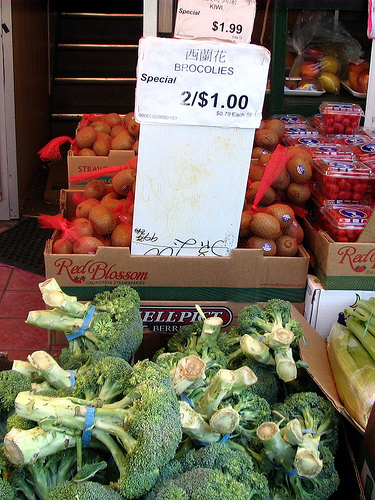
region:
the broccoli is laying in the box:
[16, 357, 179, 493]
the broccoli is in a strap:
[81, 404, 96, 443]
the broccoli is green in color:
[120, 360, 180, 497]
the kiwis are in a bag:
[233, 200, 305, 257]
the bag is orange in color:
[242, 146, 302, 261]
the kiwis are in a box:
[49, 187, 305, 311]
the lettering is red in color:
[50, 256, 148, 284]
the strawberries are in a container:
[315, 158, 370, 201]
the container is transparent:
[312, 155, 371, 201]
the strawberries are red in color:
[324, 178, 365, 199]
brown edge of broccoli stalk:
[168, 350, 224, 385]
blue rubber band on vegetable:
[74, 398, 101, 441]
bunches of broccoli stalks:
[25, 366, 165, 483]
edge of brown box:
[283, 293, 344, 433]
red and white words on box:
[149, 290, 233, 338]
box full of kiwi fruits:
[246, 194, 304, 254]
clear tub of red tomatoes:
[304, 193, 361, 246]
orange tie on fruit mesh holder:
[253, 142, 293, 211]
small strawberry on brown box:
[337, 253, 370, 276]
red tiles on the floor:
[4, 274, 39, 315]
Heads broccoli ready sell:
[38, 336, 320, 495]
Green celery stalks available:
[324, 281, 370, 436]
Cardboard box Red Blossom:
[45, 251, 176, 285]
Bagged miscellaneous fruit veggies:
[286, 40, 364, 93]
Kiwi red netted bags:
[48, 132, 130, 255]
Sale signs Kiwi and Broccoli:
[136, 0, 277, 121]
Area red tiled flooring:
[0, 258, 53, 359]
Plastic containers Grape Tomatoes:
[301, 101, 370, 191]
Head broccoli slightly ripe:
[125, 360, 191, 431]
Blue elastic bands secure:
[64, 360, 106, 451]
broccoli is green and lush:
[7, 356, 188, 498]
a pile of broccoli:
[19, 307, 317, 494]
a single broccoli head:
[19, 380, 185, 467]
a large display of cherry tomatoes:
[296, 107, 373, 234]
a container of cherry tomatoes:
[319, 104, 358, 140]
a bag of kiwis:
[249, 198, 302, 256]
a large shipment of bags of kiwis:
[72, 107, 309, 269]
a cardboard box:
[39, 251, 290, 323]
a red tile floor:
[2, 256, 51, 355]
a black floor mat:
[8, 214, 43, 271]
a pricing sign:
[148, 45, 254, 129]